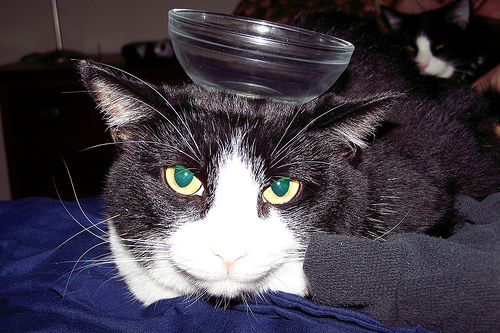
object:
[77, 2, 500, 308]
cat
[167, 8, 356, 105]
bowl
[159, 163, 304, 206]
eye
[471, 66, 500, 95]
hand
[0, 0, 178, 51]
cabinet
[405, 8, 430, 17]
sleeve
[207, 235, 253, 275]
nose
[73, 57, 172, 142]
ear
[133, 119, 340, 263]
face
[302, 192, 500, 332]
shirt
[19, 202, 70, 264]
blanket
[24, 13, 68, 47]
wall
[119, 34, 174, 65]
lamp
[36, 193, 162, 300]
whisker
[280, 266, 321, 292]
marking